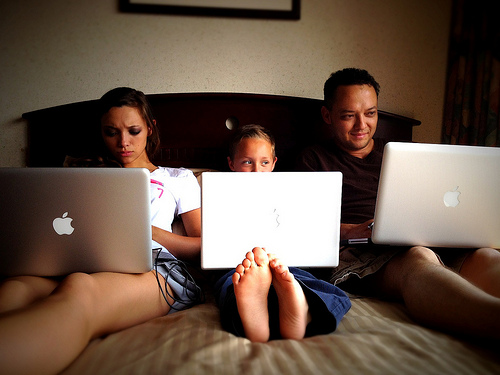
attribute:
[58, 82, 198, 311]
woman — young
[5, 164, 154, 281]
laptop — gray, silver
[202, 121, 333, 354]
girl — young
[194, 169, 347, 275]
laptop — gray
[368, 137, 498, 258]
laptop — gray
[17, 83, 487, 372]
bed — wood, striped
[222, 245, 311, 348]
feet — bare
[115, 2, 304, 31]
picture — present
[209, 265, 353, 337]
pants — blue, loose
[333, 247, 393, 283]
shorts — tan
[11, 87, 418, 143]
headboard — brown, wooden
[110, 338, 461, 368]
sheets — tan, brown, striped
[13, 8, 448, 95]
wall — tan, speckled, white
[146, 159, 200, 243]
top — white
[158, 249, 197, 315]
skirt — blue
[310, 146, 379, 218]
shirt — brown, black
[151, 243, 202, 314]
wires — black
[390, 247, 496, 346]
legs — hairy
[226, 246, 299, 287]
toes — bare